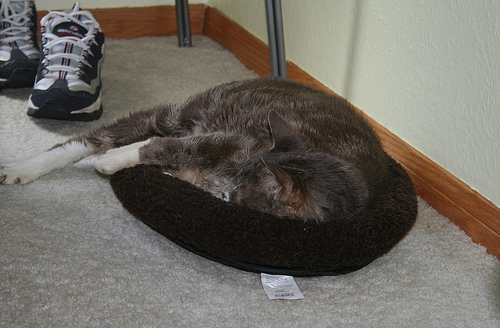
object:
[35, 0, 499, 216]
white paint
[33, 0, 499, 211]
walls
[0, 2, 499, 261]
trim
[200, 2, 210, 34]
gap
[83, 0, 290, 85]
wooden floor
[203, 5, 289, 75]
baseboard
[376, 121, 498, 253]
baseboard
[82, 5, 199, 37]
baseboard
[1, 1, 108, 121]
sneakers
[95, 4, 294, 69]
base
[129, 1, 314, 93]
chair legs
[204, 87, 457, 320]
beanscat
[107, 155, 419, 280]
pet bed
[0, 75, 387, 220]
white cat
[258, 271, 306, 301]
white tag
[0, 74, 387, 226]
pet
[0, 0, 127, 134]
shoes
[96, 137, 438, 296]
bed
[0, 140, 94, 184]
paw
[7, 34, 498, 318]
carpet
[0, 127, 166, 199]
paws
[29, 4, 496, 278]
base board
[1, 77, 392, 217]
cat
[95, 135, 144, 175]
foot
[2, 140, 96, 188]
foot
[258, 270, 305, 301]
tag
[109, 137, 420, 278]
cat bed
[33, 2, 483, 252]
moulding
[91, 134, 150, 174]
paw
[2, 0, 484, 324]
inside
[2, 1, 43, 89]
shoe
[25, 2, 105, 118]
shoe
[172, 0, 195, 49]
chair leg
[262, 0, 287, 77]
chair leg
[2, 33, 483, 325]
floor